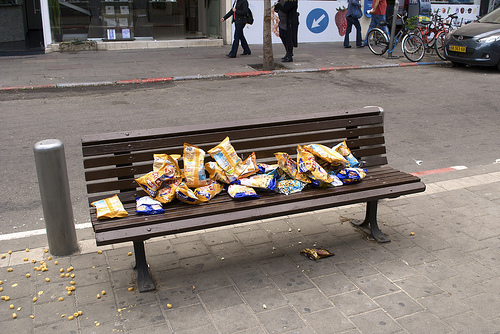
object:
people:
[271, 1, 300, 64]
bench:
[81, 105, 428, 294]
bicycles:
[365, 11, 426, 63]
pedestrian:
[219, 0, 255, 59]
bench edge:
[80, 106, 381, 147]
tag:
[448, 45, 467, 53]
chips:
[90, 140, 369, 220]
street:
[1, 44, 496, 331]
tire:
[401, 33, 426, 62]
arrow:
[310, 14, 326, 30]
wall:
[229, 0, 379, 46]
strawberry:
[334, 6, 353, 37]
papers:
[103, 4, 131, 38]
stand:
[100, 5, 135, 41]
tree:
[262, 1, 275, 70]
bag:
[90, 193, 129, 220]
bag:
[303, 143, 349, 165]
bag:
[183, 142, 208, 188]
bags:
[134, 160, 183, 199]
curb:
[0, 60, 455, 93]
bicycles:
[403, 17, 452, 60]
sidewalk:
[1, 41, 450, 92]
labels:
[104, 5, 131, 40]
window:
[50, 1, 220, 42]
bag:
[135, 195, 165, 215]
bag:
[227, 183, 260, 199]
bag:
[238, 175, 276, 191]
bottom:
[131, 235, 157, 292]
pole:
[31, 139, 79, 257]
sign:
[305, 8, 328, 33]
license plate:
[449, 45, 466, 52]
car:
[443, 3, 500, 70]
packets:
[224, 178, 260, 202]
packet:
[274, 179, 308, 196]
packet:
[331, 140, 361, 168]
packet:
[274, 151, 322, 185]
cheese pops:
[0, 227, 415, 326]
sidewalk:
[1, 162, 499, 330]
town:
[2, 0, 499, 331]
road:
[1, 62, 499, 251]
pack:
[299, 246, 336, 260]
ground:
[2, 41, 499, 331]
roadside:
[0, 51, 499, 250]